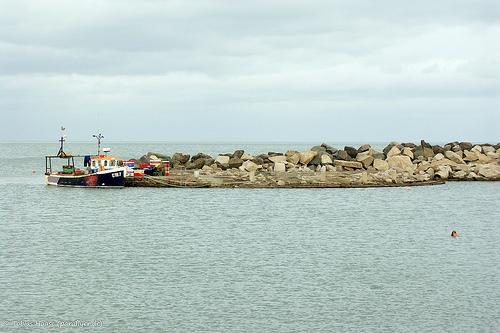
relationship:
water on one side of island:
[106, 227, 388, 319] [133, 138, 499, 190]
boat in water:
[37, 126, 164, 188] [0, 140, 499, 332]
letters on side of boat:
[108, 168, 123, 179] [37, 132, 131, 188]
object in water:
[448, 227, 458, 239] [0, 140, 499, 332]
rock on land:
[331, 152, 366, 171] [53, 128, 496, 191]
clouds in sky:
[191, 48, 348, 100] [1, 8, 498, 143]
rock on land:
[190, 153, 212, 168] [122, 145, 499, 182]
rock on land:
[376, 151, 421, 175] [91, 129, 497, 184]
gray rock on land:
[333, 149, 352, 159] [340, 172, 436, 185]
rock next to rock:
[97, 117, 297, 220] [316, 153, 378, 172]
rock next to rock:
[187, 157, 208, 172] [202, 160, 212, 176]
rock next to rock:
[209, 149, 247, 180] [266, 152, 290, 174]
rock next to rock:
[169, 137, 499, 181] [267, 151, 288, 173]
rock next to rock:
[298, 149, 316, 165] [287, 151, 302, 163]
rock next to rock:
[370, 156, 390, 172] [384, 155, 412, 170]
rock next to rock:
[370, 156, 390, 172] [356, 152, 373, 166]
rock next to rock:
[370, 156, 390, 172] [365, 163, 376, 173]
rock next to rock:
[370, 156, 390, 172] [384, 167, 396, 180]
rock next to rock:
[370, 156, 390, 172] [384, 145, 403, 159]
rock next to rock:
[172, 153, 189, 163] [188, 155, 215, 170]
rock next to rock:
[172, 153, 189, 163] [230, 146, 247, 162]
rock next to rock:
[172, 153, 189, 163] [386, 147, 414, 174]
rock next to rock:
[172, 153, 189, 163] [316, 148, 335, 168]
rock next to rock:
[445, 147, 464, 162] [429, 150, 444, 161]